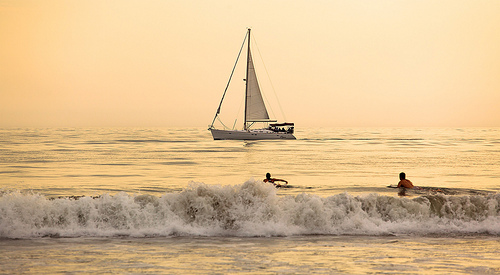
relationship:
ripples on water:
[2, 125, 496, 269] [2, 126, 498, 273]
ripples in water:
[2, 125, 496, 269] [128, 159, 238, 227]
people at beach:
[264, 168, 419, 200] [10, 220, 477, 267]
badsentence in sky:
[293, 211, 332, 241] [310, 12, 445, 112]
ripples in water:
[2, 125, 496, 269] [74, 141, 192, 259]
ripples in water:
[2, 125, 496, 269] [2, 126, 498, 273]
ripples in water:
[2, 125, 496, 269] [21, 121, 176, 197]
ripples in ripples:
[2, 125, 496, 269] [2, 125, 496, 269]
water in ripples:
[2, 126, 498, 273] [2, 125, 496, 269]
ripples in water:
[2, 125, 496, 269] [209, 194, 376, 274]